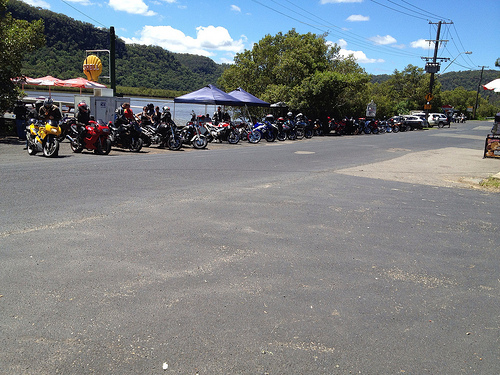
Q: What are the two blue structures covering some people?
A: Tents.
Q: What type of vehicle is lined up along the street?
A: Motorcycles.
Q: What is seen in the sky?
A: Clouds.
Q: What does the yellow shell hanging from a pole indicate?
A: Shell gas station.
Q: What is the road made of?
A: Asphalt.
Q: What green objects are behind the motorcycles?
A: Trees.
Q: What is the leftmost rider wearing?
A: Helmet.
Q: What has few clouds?
A: The sky.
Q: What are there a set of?
A: Power lines.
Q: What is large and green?
A: Tree.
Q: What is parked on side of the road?
A: Bikes.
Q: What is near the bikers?
A: A lake.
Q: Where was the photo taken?
A: On the street.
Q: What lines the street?
A: Poles.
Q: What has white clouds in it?
A: Sky.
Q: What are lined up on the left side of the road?
A: Motorcycles.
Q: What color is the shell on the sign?
A: Yellow.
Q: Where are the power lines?
A: Over the motorcycles.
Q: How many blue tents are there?
A: Two.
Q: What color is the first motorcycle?
A: Yellow.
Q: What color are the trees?
A: Green.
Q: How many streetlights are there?
A: One.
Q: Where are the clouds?
A: In the sky.